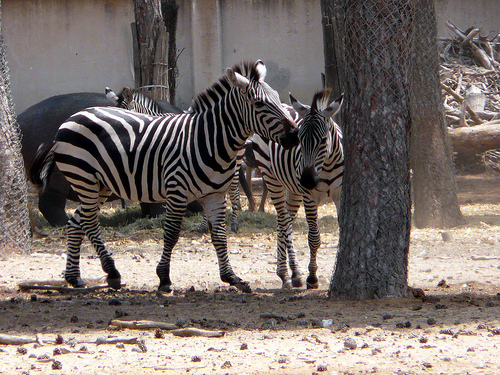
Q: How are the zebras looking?
A: Next to each other.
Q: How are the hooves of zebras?
A: Black.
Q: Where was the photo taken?
A: At a zoo.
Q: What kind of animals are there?
A: Zebras.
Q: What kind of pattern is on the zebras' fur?
A: Stripes.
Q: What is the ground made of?
A: Dirt.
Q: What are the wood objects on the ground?
A: Branches.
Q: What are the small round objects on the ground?
A: Rocks.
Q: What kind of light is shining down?
A: Sunlight.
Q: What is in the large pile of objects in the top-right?
A: Branches.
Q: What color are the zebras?
A: Black and white.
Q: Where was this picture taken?
A: A zoo.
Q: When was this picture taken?
A: During the day.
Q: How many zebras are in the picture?
A: Three.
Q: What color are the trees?
A: Brown.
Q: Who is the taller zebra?
A: Zebra on right.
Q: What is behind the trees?
A: A pile of tree branches.